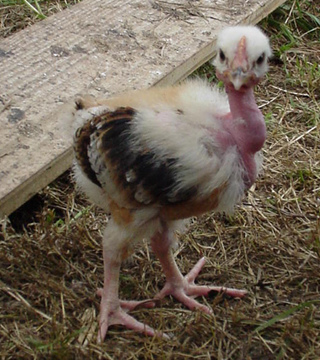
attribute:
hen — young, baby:
[46, 34, 286, 292]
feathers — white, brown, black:
[187, 88, 223, 118]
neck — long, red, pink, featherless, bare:
[226, 87, 261, 131]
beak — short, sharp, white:
[230, 54, 250, 106]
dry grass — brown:
[288, 31, 308, 83]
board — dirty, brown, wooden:
[83, 32, 127, 46]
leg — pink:
[99, 221, 129, 302]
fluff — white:
[215, 26, 259, 36]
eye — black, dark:
[210, 42, 235, 71]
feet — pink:
[94, 273, 229, 340]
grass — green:
[281, 19, 299, 53]